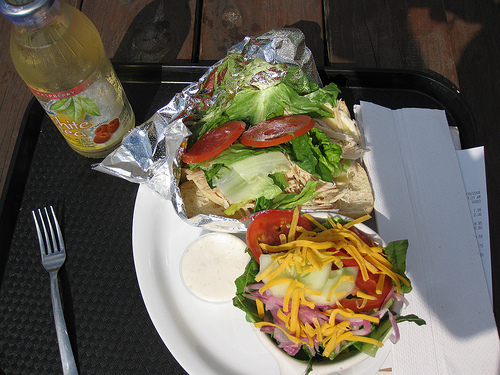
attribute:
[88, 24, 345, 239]
foil — aluminum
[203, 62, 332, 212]
lettuce — green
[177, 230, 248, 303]
cup — small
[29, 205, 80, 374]
fork — silver toned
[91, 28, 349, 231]
foil pouch — aluminum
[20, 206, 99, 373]
fork — silver, long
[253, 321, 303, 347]
cheese — shredded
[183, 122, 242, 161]
tomato slice — juicy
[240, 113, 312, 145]
tomato slice — juicy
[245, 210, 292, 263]
tomato slice — juicy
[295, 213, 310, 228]
tomato slice — juicy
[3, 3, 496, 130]
table — wooden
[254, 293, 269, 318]
cheese — shredded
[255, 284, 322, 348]
cheese — shredded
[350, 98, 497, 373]
paper — white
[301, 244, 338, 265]
cheese — shredded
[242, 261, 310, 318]
cheese — shredded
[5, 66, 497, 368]
tray — black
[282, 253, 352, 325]
salad — small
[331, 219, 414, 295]
cheese — shredded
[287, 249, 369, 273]
cheese — shredded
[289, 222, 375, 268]
cheese — shredded, small, pieces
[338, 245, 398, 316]
tomato — juicy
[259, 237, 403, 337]
cheese — shredded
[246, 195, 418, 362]
cheese — shredded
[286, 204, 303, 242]
piece — small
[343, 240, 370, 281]
piece — small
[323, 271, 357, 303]
piece — small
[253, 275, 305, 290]
piece — small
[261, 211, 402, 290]
pieces — small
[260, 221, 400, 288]
pieces — small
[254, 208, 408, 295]
pieces — small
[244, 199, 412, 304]
pieces — small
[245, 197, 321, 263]
tomato — juicy